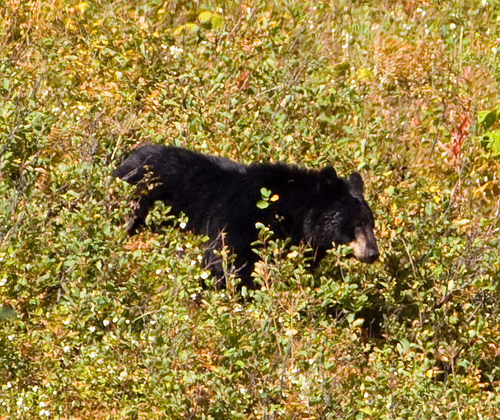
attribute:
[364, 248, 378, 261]
nose — brown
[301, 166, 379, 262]
head — dark brown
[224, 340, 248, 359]
leaf — green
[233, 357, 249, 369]
leaf — green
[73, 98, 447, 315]
dog — black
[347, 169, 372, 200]
ear — black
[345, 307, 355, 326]
leaf — green